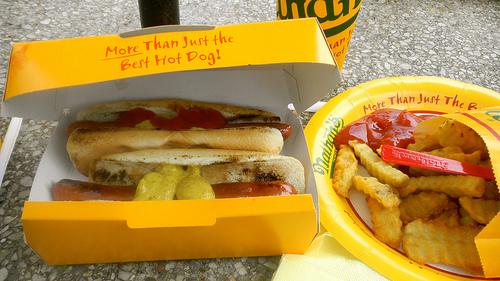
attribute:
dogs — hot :
[65, 95, 300, 199]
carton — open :
[10, 10, 338, 257]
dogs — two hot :
[54, 101, 309, 198]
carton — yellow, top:
[0, 14, 340, 276]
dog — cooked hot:
[55, 171, 117, 199]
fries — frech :
[343, 136, 470, 254]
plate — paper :
[344, 100, 410, 140]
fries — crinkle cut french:
[334, 146, 484, 268]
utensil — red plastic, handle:
[377, 142, 484, 185]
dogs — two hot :
[52, 111, 297, 204]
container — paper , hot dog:
[0, 10, 342, 253]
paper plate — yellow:
[308, 64, 498, 277]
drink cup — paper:
[279, 1, 361, 59]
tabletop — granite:
[5, 2, 493, 279]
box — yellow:
[6, 18, 344, 270]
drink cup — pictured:
[275, 1, 365, 71]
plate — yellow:
[301, 77, 484, 277]